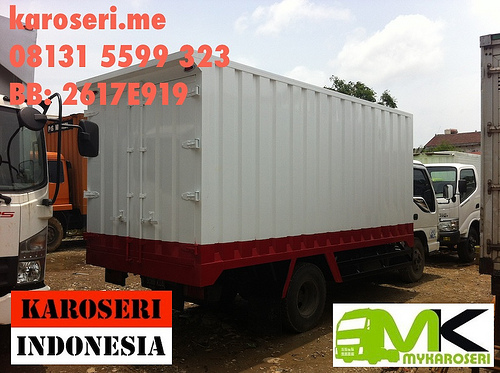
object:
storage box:
[78, 47, 416, 290]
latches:
[179, 135, 203, 150]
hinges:
[178, 189, 203, 204]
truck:
[83, 48, 441, 335]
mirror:
[440, 184, 455, 202]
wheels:
[403, 235, 427, 284]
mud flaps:
[102, 266, 131, 287]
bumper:
[425, 241, 440, 255]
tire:
[283, 262, 327, 333]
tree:
[322, 73, 401, 110]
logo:
[9, 289, 173, 366]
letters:
[150, 297, 162, 320]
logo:
[332, 303, 494, 367]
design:
[333, 306, 442, 366]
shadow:
[385, 272, 444, 290]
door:
[411, 163, 440, 231]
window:
[412, 166, 438, 216]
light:
[433, 220, 457, 234]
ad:
[0, 4, 237, 111]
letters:
[150, 11, 168, 31]